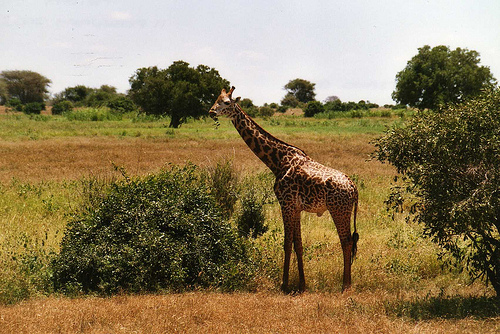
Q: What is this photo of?
A: A zoo.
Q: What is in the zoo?
A: A giraffe.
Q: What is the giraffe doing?
A: Standing.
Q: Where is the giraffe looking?
A: At the camera.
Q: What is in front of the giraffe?
A: A bush.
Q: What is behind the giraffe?
A: A tree.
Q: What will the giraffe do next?
A: Eat.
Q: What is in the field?
A: Grass.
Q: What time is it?
A: Afternoon.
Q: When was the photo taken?
A: During the daytime.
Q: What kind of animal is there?
A: Giraffe.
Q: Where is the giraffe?
A: On the ground.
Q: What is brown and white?
A: The giraffe.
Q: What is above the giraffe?
A: The sky.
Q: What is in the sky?
A: Clouds.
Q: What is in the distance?
A: Trees.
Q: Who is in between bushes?
A: A giraffe.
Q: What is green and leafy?
A: A bush.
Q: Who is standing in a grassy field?
A: A giraffe.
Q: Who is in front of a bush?
A: A giraffe.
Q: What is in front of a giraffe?
A: A bush.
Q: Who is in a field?
A: A giraffe.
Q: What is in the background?
A: Trees.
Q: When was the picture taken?
A: Daytime.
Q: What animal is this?
A: A giraffe.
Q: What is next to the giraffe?
A: A bush.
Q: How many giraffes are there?
A: One.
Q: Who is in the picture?
A: Nobody.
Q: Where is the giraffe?
A: In the field.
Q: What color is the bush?
A: Green.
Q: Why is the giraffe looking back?
A: It noticed the photographer.